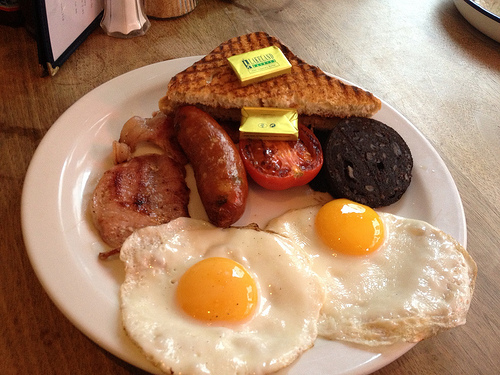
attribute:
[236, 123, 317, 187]
tomato — red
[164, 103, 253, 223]
sausage — brown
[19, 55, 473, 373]
plate — white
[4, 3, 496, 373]
table — brown